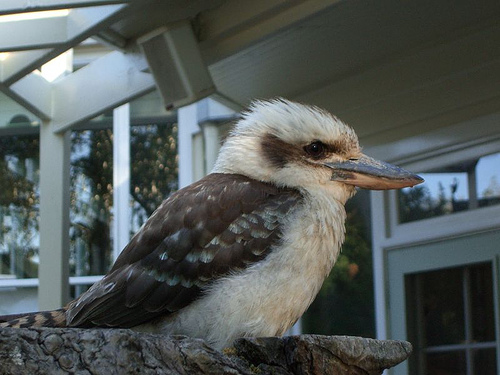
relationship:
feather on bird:
[0, 98, 357, 354] [0, 96, 422, 328]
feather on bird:
[0, 98, 357, 354] [51, 86, 425, 333]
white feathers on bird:
[167, 273, 182, 284] [0, 96, 422, 328]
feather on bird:
[115, 119, 462, 360] [99, 110, 370, 350]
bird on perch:
[0, 96, 422, 328] [0, 325, 414, 374]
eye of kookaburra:
[302, 134, 329, 164] [60, 95, 423, 329]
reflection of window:
[395, 146, 500, 224] [393, 149, 499, 219]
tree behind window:
[0, 136, 40, 280] [0, 126, 41, 279]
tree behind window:
[73, 121, 180, 219] [128, 119, 181, 243]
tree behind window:
[73, 121, 180, 219] [66, 119, 116, 299]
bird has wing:
[0, 96, 426, 352] [49, 168, 375, 365]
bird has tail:
[0, 96, 426, 352] [4, 286, 90, 330]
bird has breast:
[0, 96, 426, 352] [304, 194, 365, 286]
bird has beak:
[0, 96, 426, 352] [331, 150, 425, 190]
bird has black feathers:
[0, 96, 422, 328] [70, 175, 309, 330]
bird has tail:
[0, 96, 422, 328] [1, 309, 70, 331]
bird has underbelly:
[0, 96, 422, 328] [208, 201, 350, 341]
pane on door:
[413, 271, 468, 348] [383, 226, 498, 371]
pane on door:
[466, 260, 497, 344] [383, 226, 498, 371]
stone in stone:
[307, 332, 415, 369] [0, 325, 414, 375]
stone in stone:
[0, 325, 414, 375] [0, 325, 414, 375]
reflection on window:
[395, 146, 498, 226] [372, 152, 498, 373]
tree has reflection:
[3, 120, 40, 280] [395, 146, 498, 226]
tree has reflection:
[68, 123, 181, 269] [395, 146, 498, 226]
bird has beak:
[1, 91, 423, 349] [324, 154, 427, 194]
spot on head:
[259, 127, 307, 169] [210, 93, 425, 203]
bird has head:
[1, 91, 423, 349] [210, 93, 425, 203]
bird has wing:
[1, 91, 423, 349] [70, 172, 306, 332]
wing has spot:
[70, 172, 306, 332] [249, 228, 271, 241]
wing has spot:
[70, 172, 306, 332] [157, 247, 171, 267]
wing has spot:
[70, 172, 306, 332] [198, 251, 213, 263]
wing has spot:
[70, 172, 306, 332] [195, 219, 204, 231]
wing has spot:
[70, 172, 306, 332] [227, 218, 244, 236]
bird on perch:
[0, 96, 426, 352] [2, 317, 412, 373]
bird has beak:
[0, 96, 426, 352] [335, 146, 429, 198]